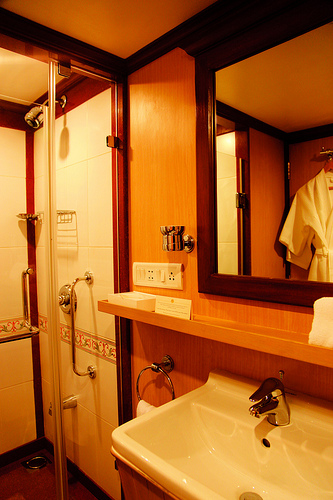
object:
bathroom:
[1, 0, 330, 498]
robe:
[279, 168, 332, 284]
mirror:
[212, 21, 333, 283]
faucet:
[246, 377, 291, 427]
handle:
[68, 270, 97, 380]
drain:
[26, 456, 47, 470]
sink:
[111, 367, 332, 500]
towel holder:
[135, 353, 176, 403]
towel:
[135, 397, 157, 416]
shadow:
[252, 415, 278, 440]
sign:
[154, 295, 194, 322]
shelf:
[97, 297, 333, 369]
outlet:
[130, 262, 183, 290]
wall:
[126, 46, 333, 419]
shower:
[0, 75, 125, 499]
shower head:
[23, 94, 68, 130]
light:
[159, 225, 197, 254]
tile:
[0, 317, 118, 367]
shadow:
[58, 107, 72, 162]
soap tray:
[17, 208, 77, 220]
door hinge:
[285, 161, 292, 182]